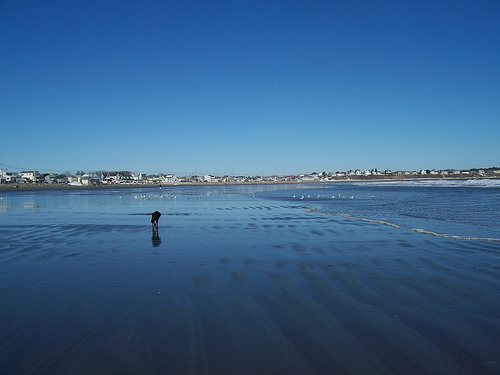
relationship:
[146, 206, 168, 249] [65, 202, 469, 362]
man on lake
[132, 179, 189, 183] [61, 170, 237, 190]
snow near buildings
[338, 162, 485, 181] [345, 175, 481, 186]
houses on land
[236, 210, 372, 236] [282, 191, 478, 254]
shadow in water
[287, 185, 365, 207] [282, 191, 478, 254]
birds on water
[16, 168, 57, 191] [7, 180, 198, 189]
house on shoreline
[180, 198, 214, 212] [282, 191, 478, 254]
animal in water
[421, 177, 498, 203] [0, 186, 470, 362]
wave in lake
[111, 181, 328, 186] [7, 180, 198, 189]
sand on shoreline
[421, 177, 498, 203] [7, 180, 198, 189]
wave on shoreline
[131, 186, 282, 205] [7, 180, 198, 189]
seagulls on shoreline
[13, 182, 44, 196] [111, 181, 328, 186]
dog on sand